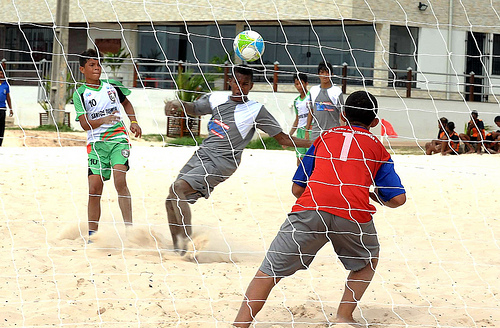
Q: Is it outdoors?
A: Yes, it is outdoors.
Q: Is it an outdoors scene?
A: Yes, it is outdoors.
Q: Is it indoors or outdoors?
A: It is outdoors.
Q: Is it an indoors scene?
A: No, it is outdoors.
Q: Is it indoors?
A: No, it is outdoors.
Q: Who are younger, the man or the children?
A: The children are younger than the man.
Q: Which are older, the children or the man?
A: The man are older than the children.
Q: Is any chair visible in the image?
A: No, there are no chairs.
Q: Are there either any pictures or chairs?
A: No, there are no chairs or pictures.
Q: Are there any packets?
A: No, there are no packets.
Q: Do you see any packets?
A: No, there are no packets.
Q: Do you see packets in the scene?
A: No, there are no packets.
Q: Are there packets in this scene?
A: No, there are no packets.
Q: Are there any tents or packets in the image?
A: No, there are no packets or tents.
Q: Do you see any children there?
A: Yes, there are children.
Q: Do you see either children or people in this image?
A: Yes, there are children.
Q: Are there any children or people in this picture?
A: Yes, there are children.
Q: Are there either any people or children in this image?
A: Yes, there are children.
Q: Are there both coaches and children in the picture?
A: No, there are children but no coaches.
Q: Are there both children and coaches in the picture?
A: No, there are children but no coaches.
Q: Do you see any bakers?
A: No, there are no bakers.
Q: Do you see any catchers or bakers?
A: No, there are no bakers or catchers.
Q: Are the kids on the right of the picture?
A: Yes, the kids are on the right of the image.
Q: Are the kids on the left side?
A: No, the kids are on the right of the image.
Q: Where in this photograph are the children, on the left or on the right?
A: The children are on the right of the image.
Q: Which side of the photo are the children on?
A: The children are on the right of the image.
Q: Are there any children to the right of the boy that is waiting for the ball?
A: Yes, there are children to the right of the boy.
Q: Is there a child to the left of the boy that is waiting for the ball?
A: No, the children are to the right of the boy.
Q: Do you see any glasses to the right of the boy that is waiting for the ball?
A: No, there are children to the right of the boy.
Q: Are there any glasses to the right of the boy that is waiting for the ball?
A: No, there are children to the right of the boy.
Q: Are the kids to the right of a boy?
A: Yes, the kids are to the right of a boy.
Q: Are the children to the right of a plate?
A: No, the children are to the right of a boy.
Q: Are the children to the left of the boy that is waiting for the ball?
A: No, the children are to the right of the boy.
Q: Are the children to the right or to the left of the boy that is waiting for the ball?
A: The children are to the right of the boy.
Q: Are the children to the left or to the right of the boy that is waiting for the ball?
A: The children are to the right of the boy.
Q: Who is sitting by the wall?
A: The children are sitting by the wall.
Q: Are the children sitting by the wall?
A: Yes, the children are sitting by the wall.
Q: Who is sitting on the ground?
A: The children are sitting on the ground.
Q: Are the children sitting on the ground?
A: Yes, the children are sitting on the ground.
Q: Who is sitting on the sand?
A: The children are sitting on the sand.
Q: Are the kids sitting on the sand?
A: Yes, the kids are sitting on the sand.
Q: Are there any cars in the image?
A: No, there are no cars.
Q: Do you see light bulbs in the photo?
A: No, there are no light bulbs.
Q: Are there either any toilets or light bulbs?
A: No, there are no light bulbs or toilets.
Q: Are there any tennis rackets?
A: No, there are no tennis rackets.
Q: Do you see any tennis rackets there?
A: No, there are no tennis rackets.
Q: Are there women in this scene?
A: No, there are no women.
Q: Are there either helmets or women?
A: No, there are no women or helmets.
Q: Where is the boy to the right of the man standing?
A: The boy is standing in the sand.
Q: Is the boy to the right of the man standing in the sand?
A: Yes, the boy is standing in the sand.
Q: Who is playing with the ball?
A: The boy is playing with the ball.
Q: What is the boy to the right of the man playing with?
A: The boy is playing with a ball.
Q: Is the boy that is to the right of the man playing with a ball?
A: Yes, the boy is playing with a ball.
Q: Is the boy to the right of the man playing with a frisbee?
A: No, the boy is playing with a ball.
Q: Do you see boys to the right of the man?
A: Yes, there is a boy to the right of the man.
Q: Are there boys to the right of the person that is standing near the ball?
A: Yes, there is a boy to the right of the man.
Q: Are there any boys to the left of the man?
A: No, the boy is to the right of the man.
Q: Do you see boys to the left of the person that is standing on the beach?
A: No, the boy is to the right of the man.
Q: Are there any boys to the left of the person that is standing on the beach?
A: No, the boy is to the right of the man.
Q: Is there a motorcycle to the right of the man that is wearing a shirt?
A: No, there is a boy to the right of the man.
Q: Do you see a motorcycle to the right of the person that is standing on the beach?
A: No, there is a boy to the right of the man.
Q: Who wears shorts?
A: The boy wears shorts.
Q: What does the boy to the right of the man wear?
A: The boy wears shorts.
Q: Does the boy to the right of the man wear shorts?
A: Yes, the boy wears shorts.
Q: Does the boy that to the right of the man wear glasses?
A: No, the boy wears shorts.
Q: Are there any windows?
A: Yes, there are windows.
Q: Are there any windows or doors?
A: Yes, there are windows.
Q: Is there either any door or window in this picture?
A: Yes, there are windows.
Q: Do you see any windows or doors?
A: Yes, there are windows.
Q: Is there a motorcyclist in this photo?
A: No, there are no bikers.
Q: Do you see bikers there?
A: No, there are no bikers.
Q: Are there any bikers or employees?
A: No, there are no bikers or employees.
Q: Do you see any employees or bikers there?
A: No, there are no bikers or employees.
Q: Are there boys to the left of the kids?
A: Yes, there is a boy to the left of the kids.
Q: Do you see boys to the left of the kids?
A: Yes, there is a boy to the left of the kids.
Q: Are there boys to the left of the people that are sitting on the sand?
A: Yes, there is a boy to the left of the kids.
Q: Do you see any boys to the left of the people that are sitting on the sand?
A: Yes, there is a boy to the left of the kids.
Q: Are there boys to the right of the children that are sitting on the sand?
A: No, the boy is to the left of the children.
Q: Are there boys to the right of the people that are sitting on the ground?
A: No, the boy is to the left of the children.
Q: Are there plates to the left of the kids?
A: No, there is a boy to the left of the kids.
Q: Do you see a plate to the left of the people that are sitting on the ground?
A: No, there is a boy to the left of the kids.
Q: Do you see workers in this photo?
A: No, there are no workers.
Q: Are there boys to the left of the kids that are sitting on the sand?
A: Yes, there is a boy to the left of the kids.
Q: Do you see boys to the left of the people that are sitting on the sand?
A: Yes, there is a boy to the left of the kids.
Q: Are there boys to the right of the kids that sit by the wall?
A: No, the boy is to the left of the kids.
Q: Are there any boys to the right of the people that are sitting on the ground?
A: No, the boy is to the left of the kids.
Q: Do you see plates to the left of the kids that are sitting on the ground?
A: No, there is a boy to the left of the kids.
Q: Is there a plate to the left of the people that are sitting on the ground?
A: No, there is a boy to the left of the kids.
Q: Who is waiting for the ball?
A: The boy is waiting for the ball.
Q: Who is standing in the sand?
A: The boy is standing in the sand.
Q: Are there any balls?
A: Yes, there is a ball.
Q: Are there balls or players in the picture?
A: Yes, there is a ball.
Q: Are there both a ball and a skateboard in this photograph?
A: No, there is a ball but no skateboards.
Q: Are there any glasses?
A: No, there are no glasses.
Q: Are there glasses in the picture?
A: No, there are no glasses.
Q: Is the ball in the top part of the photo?
A: Yes, the ball is in the top of the image.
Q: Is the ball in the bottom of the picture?
A: No, the ball is in the top of the image.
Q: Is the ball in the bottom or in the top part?
A: The ball is in the top of the image.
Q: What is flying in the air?
A: The ball is flying in the air.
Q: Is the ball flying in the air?
A: Yes, the ball is flying in the air.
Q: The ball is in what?
A: The ball is in the air.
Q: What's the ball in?
A: The ball is in the air.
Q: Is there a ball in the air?
A: Yes, there is a ball in the air.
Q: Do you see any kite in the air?
A: No, there is a ball in the air.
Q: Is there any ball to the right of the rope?
A: Yes, there is a ball to the right of the rope.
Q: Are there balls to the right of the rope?
A: Yes, there is a ball to the right of the rope.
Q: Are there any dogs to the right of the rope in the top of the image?
A: No, there is a ball to the right of the rope.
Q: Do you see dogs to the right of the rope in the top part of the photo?
A: No, there is a ball to the right of the rope.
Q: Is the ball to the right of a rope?
A: Yes, the ball is to the right of a rope.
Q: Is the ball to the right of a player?
A: No, the ball is to the right of a rope.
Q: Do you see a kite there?
A: No, there are no kites.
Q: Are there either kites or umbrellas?
A: No, there are no kites or umbrellas.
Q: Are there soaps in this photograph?
A: No, there are no soaps.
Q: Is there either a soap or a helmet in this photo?
A: No, there are no soaps or helmets.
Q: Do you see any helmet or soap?
A: No, there are no soaps or helmets.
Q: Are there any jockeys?
A: No, there are no jockeys.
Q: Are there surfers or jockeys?
A: No, there are no jockeys or surfers.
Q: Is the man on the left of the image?
A: Yes, the man is on the left of the image.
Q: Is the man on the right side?
A: No, the man is on the left of the image.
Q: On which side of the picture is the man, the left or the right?
A: The man is on the left of the image.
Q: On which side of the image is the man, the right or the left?
A: The man is on the left of the image.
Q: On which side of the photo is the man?
A: The man is on the left of the image.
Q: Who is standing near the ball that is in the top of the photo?
A: The man is standing near the ball.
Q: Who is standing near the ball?
A: The man is standing near the ball.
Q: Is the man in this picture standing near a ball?
A: Yes, the man is standing near a ball.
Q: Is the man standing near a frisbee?
A: No, the man is standing near a ball.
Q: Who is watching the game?
A: The man is watching the game.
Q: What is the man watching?
A: The man is watching the game.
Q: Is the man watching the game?
A: Yes, the man is watching the game.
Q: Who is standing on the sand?
A: The man is standing on the sand.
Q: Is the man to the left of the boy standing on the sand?
A: Yes, the man is standing on the sand.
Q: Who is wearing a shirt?
A: The man is wearing a shirt.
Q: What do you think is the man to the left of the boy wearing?
A: The man is wearing a shirt.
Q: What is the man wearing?
A: The man is wearing a shirt.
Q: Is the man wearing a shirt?
A: Yes, the man is wearing a shirt.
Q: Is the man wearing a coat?
A: No, the man is wearing a shirt.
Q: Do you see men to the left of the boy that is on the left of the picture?
A: Yes, there is a man to the left of the boy.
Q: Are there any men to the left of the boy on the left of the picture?
A: Yes, there is a man to the left of the boy.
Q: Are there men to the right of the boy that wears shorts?
A: No, the man is to the left of the boy.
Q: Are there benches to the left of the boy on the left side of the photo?
A: No, there is a man to the left of the boy.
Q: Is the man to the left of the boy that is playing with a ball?
A: Yes, the man is to the left of the boy.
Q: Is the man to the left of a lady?
A: No, the man is to the left of the boy.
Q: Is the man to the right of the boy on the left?
A: No, the man is to the left of the boy.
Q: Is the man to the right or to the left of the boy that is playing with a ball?
A: The man is to the left of the boy.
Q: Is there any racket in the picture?
A: No, there are no rackets.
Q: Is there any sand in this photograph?
A: Yes, there is sand.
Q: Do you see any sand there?
A: Yes, there is sand.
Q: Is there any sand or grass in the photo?
A: Yes, there is sand.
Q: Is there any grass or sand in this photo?
A: Yes, there is sand.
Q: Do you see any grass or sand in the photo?
A: Yes, there is sand.